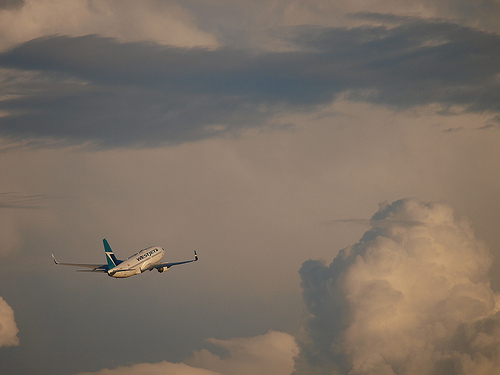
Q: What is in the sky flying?
A: A plane.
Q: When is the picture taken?
A: Dusk.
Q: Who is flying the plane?
A: The pilot.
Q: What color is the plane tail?
A: Blue.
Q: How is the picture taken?
A: Aerial view.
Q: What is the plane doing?
A: Flying.